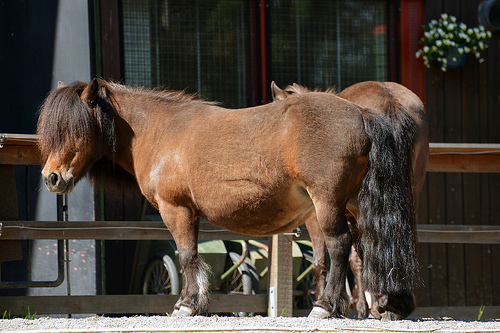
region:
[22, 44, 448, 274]
this is a horse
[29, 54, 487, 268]
the horse looks funny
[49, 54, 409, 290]
the horse is miniature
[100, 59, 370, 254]
the horse is light brown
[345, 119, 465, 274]
the horse has a long tail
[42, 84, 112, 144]
the horse has long hair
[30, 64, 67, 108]
the horse man is dark brown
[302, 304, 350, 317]
the horse hooves are lighter in color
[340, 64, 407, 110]
there is another horse here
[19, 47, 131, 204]
head of a horse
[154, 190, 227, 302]
leg of a horse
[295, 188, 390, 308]
leg of a horse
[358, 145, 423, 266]
tail of a horse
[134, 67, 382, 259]
body of a horse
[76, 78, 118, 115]
ear of a horse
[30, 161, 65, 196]
nose of a horse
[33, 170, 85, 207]
mouth of a horse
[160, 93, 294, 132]
back of a horse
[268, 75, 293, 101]
ear of a horse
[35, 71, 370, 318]
this is the horse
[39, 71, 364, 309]
the horse is brown in color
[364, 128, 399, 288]
this is the tail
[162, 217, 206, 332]
these are the legs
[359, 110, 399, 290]
the tail is black in color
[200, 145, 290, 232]
the belly is fat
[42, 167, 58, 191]
this is the nose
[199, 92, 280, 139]
this is the back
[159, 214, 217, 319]
the legs are short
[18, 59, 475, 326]
two small brown ponies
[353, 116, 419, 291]
long black hair on the tail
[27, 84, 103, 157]
dark hair covering the face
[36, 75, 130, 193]
head turned to the side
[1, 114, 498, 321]
small wooden fence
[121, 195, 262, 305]
a wheelbarrow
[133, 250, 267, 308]
two wheels on the bottom of the wheelbarrow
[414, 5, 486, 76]
plant in a planter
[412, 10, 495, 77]
planter hanging on the wall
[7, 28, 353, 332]
a horse standing outside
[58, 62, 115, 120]
an ear on the horse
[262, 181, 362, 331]
a leg on the horse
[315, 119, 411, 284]
a tail on the horse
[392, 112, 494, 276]
a brown wooden fence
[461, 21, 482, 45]
white flower in a pot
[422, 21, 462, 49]
white flower in a pot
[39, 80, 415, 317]
large brown hairy horse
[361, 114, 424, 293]
long large black tail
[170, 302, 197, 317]
large grey thick hoof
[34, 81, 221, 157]
long brown coarse mane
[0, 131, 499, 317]
large wide brown wooden rail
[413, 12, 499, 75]
large leafy green plant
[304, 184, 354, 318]
large thick brown leg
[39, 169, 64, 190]
large dark round nostrils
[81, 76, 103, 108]
large pointy brown ear